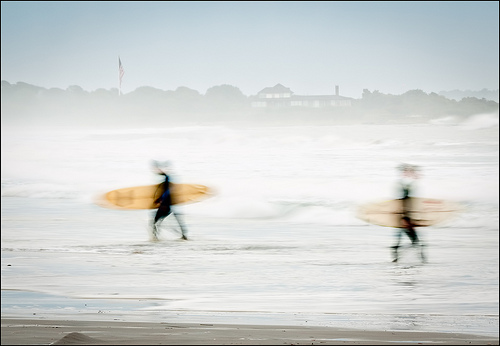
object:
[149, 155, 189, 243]
person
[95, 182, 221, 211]
surfboard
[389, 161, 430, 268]
person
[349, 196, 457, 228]
surfboard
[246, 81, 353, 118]
building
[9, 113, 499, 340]
sea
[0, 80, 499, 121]
tree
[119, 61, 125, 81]
flag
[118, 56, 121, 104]
post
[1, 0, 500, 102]
sky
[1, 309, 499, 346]
sand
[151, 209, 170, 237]
leg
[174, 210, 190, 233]
leg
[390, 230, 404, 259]
leg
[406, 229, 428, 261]
leg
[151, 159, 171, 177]
head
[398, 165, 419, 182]
head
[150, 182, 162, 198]
arm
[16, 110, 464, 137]
beach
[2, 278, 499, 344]
shore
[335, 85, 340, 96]
chimney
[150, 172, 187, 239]
wetsuit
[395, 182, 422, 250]
wetsuit